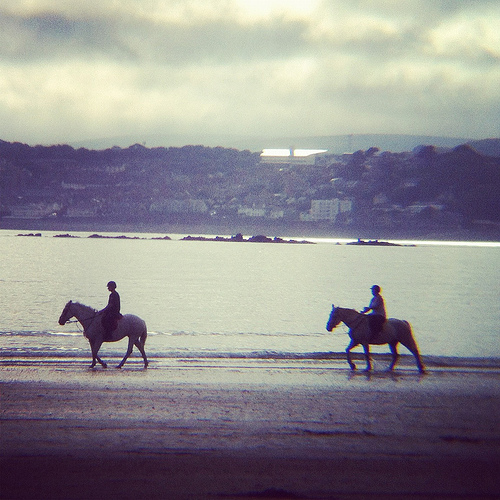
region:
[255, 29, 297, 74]
part of a cloud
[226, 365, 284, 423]
part of a shore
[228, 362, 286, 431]
edge of a shore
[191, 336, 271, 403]
part of a beach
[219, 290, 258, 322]
part of a water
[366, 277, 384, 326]
this is a man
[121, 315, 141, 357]
this is a horse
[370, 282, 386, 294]
this is a helmet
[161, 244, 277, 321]
this is a water area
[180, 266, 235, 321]
the water is calm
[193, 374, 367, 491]
this is the beach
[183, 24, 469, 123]
these are clouds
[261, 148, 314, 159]
this is a building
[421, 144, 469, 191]
these are the trees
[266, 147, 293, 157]
the roof is white in color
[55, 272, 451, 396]
Two people are on horseback.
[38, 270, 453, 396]
Two horses with riders.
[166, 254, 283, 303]
The water is bright.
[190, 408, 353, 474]
Sand is on the beach.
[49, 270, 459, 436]
They are riding on the beach.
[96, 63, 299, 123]
The sky is overcast.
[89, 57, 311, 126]
The sky is dull.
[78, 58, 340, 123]
The sky is cloudy.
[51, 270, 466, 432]
They are on a beach.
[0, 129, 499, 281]
Land is in the background.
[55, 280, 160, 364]
this is a horse rider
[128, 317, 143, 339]
the horse is white in color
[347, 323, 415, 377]
the horse is in motion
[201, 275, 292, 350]
the sea is calm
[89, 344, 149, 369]
the legs are strong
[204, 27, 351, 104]
the sky is grey in color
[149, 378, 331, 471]
sand is all over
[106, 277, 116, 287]
he is wearing a helmet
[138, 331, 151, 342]
this is the tail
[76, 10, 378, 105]
The sky is dull.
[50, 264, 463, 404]
Two people are riding horses.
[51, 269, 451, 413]
They are riding horses on the beach.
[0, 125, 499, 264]
Land is in the distance.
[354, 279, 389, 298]
The person is wearing a hat.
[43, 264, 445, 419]
The horses are walking on the beach.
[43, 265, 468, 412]
Two horses are walking.